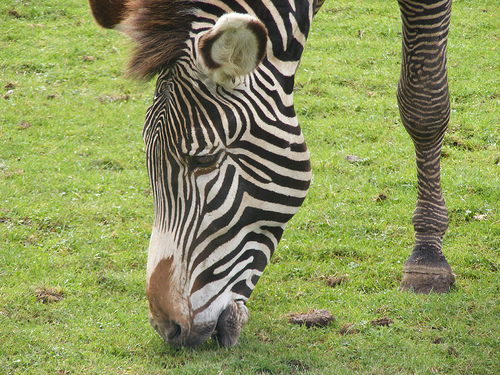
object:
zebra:
[85, 1, 461, 353]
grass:
[0, 104, 134, 375]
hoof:
[398, 247, 456, 296]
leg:
[391, 0, 458, 295]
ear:
[199, 9, 269, 86]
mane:
[121, 0, 197, 84]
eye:
[181, 145, 226, 172]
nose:
[145, 312, 196, 344]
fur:
[250, 107, 279, 136]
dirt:
[290, 310, 331, 326]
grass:
[273, 296, 500, 375]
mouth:
[201, 304, 239, 347]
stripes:
[202, 206, 237, 242]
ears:
[89, 0, 128, 31]